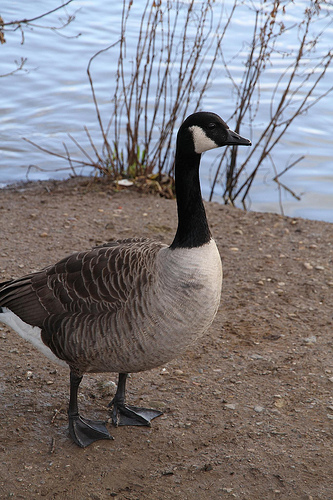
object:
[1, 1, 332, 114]
water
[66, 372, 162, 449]
feet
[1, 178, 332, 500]
ground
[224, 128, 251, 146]
beak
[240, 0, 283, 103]
vegetation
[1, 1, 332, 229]
background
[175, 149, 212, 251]
neck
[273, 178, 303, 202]
reflection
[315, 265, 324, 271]
rocks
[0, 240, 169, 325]
back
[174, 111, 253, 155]
head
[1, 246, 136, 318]
wing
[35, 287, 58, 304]
feather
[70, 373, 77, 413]
legs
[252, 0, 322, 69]
leaves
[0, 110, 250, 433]
bird